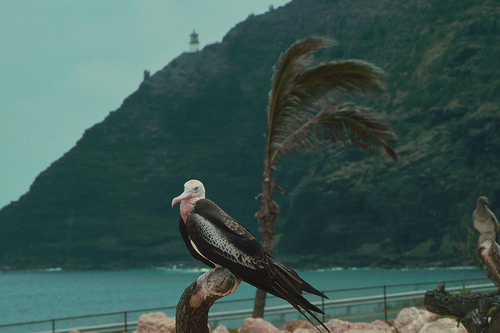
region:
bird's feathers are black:
[180, 200, 319, 322]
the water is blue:
[24, 268, 116, 303]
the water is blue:
[80, 273, 165, 308]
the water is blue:
[21, 258, 203, 330]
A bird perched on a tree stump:
[170, 178, 338, 332]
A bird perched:
[470, 195, 498, 247]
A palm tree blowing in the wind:
[251, 35, 398, 317]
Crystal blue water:
[0, 265, 497, 331]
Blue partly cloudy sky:
[0, 0, 293, 212]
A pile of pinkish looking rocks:
[135, 306, 470, 331]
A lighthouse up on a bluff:
[188, 28, 198, 53]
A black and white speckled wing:
[186, 210, 287, 287]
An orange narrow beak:
[170, 191, 193, 204]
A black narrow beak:
[485, 199, 492, 208]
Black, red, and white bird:
[168, 150, 342, 330]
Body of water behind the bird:
[0, 265, 497, 331]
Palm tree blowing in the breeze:
[252, 34, 414, 322]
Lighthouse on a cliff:
[178, 26, 207, 53]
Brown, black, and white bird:
[466, 190, 498, 257]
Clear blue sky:
[2, 1, 288, 209]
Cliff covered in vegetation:
[0, 3, 496, 275]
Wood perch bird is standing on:
[175, 265, 247, 331]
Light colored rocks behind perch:
[129, 308, 474, 331]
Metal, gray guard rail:
[0, 274, 499, 331]